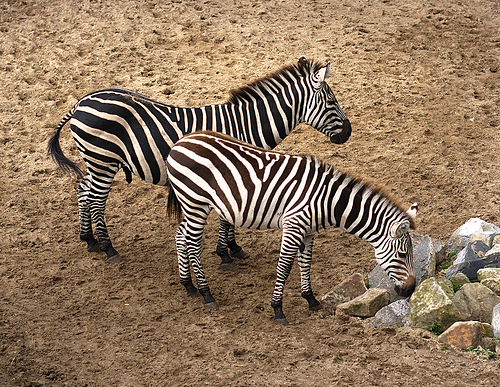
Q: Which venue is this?
A: This is a field.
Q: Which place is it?
A: It is a field.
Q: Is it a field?
A: Yes, it is a field.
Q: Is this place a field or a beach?
A: It is a field.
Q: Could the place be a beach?
A: No, it is a field.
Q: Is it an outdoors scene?
A: Yes, it is outdoors.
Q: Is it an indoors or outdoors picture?
A: It is outdoors.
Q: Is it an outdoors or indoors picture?
A: It is outdoors.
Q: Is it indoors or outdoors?
A: It is outdoors.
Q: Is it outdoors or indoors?
A: It is outdoors.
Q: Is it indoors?
A: No, it is outdoors.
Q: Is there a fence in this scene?
A: No, there are no fences.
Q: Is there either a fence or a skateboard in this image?
A: No, there are no fences or skateboards.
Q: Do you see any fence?
A: No, there are no fences.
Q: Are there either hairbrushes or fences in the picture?
A: No, there are no fences or hairbrushes.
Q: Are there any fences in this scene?
A: No, there are no fences.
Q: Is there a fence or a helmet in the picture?
A: No, there are no fences or helmets.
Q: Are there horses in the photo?
A: No, there are no horses.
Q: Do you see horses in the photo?
A: No, there are no horses.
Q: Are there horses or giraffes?
A: No, there are no horses or giraffes.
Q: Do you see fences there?
A: No, there are no fences.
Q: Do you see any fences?
A: No, there are no fences.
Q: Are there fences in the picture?
A: No, there are no fences.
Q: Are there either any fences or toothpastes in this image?
A: No, there are no fences or toothpastes.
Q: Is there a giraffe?
A: No, there are no giraffes.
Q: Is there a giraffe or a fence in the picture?
A: No, there are no giraffes or fences.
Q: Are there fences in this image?
A: No, there are no fences.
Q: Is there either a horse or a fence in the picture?
A: No, there are no fences or horses.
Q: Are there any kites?
A: No, there are no kites.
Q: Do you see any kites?
A: No, there are no kites.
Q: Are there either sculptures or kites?
A: No, there are no kites or sculptures.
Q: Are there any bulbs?
A: No, there are no bulbs.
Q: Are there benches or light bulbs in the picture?
A: No, there are no light bulbs or benches.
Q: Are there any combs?
A: No, there are no combs.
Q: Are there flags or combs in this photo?
A: No, there are no combs or flags.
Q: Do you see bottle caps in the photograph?
A: No, there are no bottle caps.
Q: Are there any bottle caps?
A: No, there are no bottle caps.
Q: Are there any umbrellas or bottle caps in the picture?
A: No, there are no bottle caps or umbrellas.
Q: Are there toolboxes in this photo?
A: No, there are no toolboxes.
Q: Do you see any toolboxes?
A: No, there are no toolboxes.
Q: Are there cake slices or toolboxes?
A: No, there are no toolboxes or cake slices.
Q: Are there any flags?
A: No, there are no flags.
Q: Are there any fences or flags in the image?
A: No, there are no flags or fences.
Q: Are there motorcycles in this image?
A: No, there are no motorcycles.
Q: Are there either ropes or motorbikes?
A: No, there are no motorbikes or ropes.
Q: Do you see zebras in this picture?
A: Yes, there is a zebra.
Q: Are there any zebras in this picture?
A: Yes, there is a zebra.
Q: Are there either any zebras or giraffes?
A: Yes, there is a zebra.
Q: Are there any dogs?
A: No, there are no dogs.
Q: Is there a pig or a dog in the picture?
A: No, there are no dogs or pigs.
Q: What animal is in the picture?
A: The animal is a zebra.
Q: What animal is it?
A: The animal is a zebra.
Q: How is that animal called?
A: That is a zebra.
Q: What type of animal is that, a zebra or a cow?
A: That is a zebra.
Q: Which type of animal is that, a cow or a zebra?
A: That is a zebra.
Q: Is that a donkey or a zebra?
A: That is a zebra.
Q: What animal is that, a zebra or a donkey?
A: That is a zebra.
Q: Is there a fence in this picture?
A: No, there are no fences.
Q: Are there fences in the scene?
A: No, there are no fences.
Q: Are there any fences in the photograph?
A: No, there are no fences.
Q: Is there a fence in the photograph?
A: No, there are no fences.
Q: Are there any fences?
A: No, there are no fences.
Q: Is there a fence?
A: No, there are no fences.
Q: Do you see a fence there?
A: No, there are no fences.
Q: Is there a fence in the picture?
A: No, there are no fences.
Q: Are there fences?
A: No, there are no fences.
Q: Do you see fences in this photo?
A: No, there are no fences.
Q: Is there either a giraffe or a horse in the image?
A: No, there are no horses or giraffes.